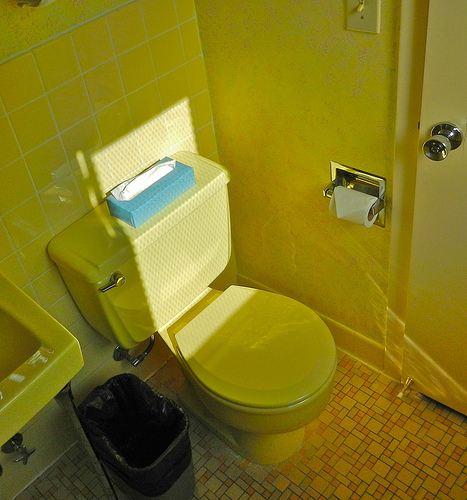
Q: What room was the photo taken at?
A: It was taken at the bathroom.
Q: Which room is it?
A: It is a bathroom.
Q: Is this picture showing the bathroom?
A: Yes, it is showing the bathroom.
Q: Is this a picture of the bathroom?
A: Yes, it is showing the bathroom.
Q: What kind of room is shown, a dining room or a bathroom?
A: It is a bathroom.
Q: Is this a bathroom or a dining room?
A: It is a bathroom.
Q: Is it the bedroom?
A: No, it is the bathroom.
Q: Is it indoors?
A: Yes, it is indoors.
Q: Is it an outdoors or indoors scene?
A: It is indoors.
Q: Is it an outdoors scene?
A: No, it is indoors.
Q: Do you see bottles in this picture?
A: No, there are no bottles.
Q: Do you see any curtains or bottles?
A: No, there are no bottles or curtains.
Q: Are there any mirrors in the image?
A: No, there are no mirrors.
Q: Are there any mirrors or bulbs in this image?
A: No, there are no mirrors or bulbs.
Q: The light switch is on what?
A: The light switch is on the wall.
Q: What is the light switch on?
A: The light switch is on the wall.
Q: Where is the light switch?
A: The light switch is in the bathroom.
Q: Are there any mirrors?
A: No, there are no mirrors.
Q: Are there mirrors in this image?
A: No, there are no mirrors.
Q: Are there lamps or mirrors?
A: No, there are no mirrors or lamps.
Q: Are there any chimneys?
A: No, there are no chimneys.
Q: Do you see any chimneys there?
A: No, there are no chimneys.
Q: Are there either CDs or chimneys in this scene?
A: No, there are no chimneys or cds.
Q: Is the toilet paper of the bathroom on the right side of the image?
A: Yes, the toilet paper is on the right of the image.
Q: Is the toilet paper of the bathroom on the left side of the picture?
A: No, the toilet paper is on the right of the image.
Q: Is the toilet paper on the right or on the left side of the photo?
A: The toilet paper is on the right of the image.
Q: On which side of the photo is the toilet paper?
A: The toilet paper is on the right of the image.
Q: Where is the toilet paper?
A: The toilet paper is in the bathroom.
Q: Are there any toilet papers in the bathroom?
A: Yes, there is a toilet paper in the bathroom.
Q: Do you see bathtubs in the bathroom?
A: No, there is a toilet paper in the bathroom.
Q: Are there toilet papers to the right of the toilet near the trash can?
A: Yes, there is a toilet paper to the right of the toilet.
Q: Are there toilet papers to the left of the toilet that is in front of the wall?
A: No, the toilet paper is to the right of the toilet.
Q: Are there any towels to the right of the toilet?
A: No, there is a toilet paper to the right of the toilet.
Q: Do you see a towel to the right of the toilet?
A: No, there is a toilet paper to the right of the toilet.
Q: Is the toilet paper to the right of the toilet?
A: Yes, the toilet paper is to the right of the toilet.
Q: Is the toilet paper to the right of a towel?
A: No, the toilet paper is to the right of the toilet.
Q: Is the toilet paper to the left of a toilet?
A: No, the toilet paper is to the right of a toilet.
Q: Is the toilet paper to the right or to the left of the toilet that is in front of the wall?
A: The toilet paper is to the right of the toilet.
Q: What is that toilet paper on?
A: The toilet paper is on the wall.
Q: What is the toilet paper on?
A: The toilet paper is on the wall.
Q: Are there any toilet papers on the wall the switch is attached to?
A: Yes, there is a toilet paper on the wall.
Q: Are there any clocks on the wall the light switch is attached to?
A: No, there is a toilet paper on the wall.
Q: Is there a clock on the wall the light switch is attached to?
A: No, there is a toilet paper on the wall.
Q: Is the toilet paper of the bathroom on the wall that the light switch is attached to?
A: Yes, the toilet paper is on the wall.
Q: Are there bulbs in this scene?
A: No, there are no bulbs.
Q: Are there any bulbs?
A: No, there are no bulbs.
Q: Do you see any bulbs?
A: No, there are no bulbs.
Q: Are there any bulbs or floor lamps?
A: No, there are no bulbs or floor lamps.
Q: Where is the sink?
A: The sink is in the bathroom.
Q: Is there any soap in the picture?
A: No, there are no soaps.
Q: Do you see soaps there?
A: No, there are no soaps.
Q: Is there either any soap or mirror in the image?
A: No, there are no soaps or mirrors.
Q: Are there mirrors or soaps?
A: No, there are no soaps or mirrors.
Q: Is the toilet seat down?
A: Yes, the toilet seat is down.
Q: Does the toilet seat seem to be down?
A: Yes, the toilet seat is down.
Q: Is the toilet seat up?
A: No, the toilet seat is down.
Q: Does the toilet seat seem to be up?
A: No, the toilet seat is down.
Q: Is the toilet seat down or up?
A: The toilet seat is down.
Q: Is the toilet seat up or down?
A: The toilet seat is down.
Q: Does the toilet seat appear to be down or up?
A: The toilet seat is down.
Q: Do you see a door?
A: Yes, there is a door.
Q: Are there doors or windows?
A: Yes, there is a door.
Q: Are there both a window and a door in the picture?
A: No, there is a door but no windows.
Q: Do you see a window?
A: No, there are no windows.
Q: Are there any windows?
A: No, there are no windows.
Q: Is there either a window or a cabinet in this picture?
A: No, there are no windows or cabinets.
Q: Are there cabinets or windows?
A: No, there are no windows or cabinets.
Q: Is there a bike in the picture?
A: No, there are no bikes.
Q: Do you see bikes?
A: No, there are no bikes.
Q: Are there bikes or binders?
A: No, there are no bikes or binders.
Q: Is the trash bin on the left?
A: Yes, the trash bin is on the left of the image.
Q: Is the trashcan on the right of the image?
A: No, the trashcan is on the left of the image.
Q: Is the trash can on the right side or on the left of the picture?
A: The trash can is on the left of the image.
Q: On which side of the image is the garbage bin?
A: The garbage bin is on the left of the image.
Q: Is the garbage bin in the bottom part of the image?
A: Yes, the garbage bin is in the bottom of the image.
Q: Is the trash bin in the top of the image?
A: No, the trash bin is in the bottom of the image.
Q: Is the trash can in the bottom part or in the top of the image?
A: The trash can is in the bottom of the image.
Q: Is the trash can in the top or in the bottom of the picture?
A: The trash can is in the bottom of the image.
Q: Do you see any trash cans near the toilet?
A: Yes, there is a trash can near the toilet.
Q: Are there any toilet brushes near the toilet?
A: No, there is a trash can near the toilet.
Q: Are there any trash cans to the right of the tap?
A: Yes, there is a trash can to the right of the tap.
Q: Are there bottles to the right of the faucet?
A: No, there is a trash can to the right of the faucet.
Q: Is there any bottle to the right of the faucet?
A: No, there is a trash can to the right of the faucet.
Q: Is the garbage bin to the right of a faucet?
A: Yes, the garbage bin is to the right of a faucet.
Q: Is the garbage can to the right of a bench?
A: No, the garbage can is to the right of a faucet.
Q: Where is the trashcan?
A: The trashcan is in the bathroom.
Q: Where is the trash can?
A: The trashcan is in the bathroom.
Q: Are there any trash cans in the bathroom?
A: Yes, there is a trash can in the bathroom.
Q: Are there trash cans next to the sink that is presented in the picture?
A: Yes, there is a trash can next to the sink.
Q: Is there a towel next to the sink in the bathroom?
A: No, there is a trash can next to the sink.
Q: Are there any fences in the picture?
A: No, there are no fences.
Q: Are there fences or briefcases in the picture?
A: No, there are no fences or briefcases.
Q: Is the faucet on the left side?
A: Yes, the faucet is on the left of the image.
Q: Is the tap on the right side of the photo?
A: No, the tap is on the left of the image.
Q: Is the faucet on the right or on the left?
A: The faucet is on the left of the image.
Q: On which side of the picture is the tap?
A: The tap is on the left of the image.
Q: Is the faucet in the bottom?
A: Yes, the faucet is in the bottom of the image.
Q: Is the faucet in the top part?
A: No, the faucet is in the bottom of the image.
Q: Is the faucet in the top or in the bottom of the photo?
A: The faucet is in the bottom of the image.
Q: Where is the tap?
A: The tap is in the bathroom.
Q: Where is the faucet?
A: The tap is in the bathroom.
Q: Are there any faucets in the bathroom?
A: Yes, there is a faucet in the bathroom.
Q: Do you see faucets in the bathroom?
A: Yes, there is a faucet in the bathroom.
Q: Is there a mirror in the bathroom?
A: No, there is a faucet in the bathroom.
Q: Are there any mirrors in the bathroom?
A: No, there is a faucet in the bathroom.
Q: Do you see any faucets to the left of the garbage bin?
A: Yes, there is a faucet to the left of the garbage bin.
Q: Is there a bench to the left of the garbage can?
A: No, there is a faucet to the left of the garbage can.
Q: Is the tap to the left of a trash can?
A: Yes, the tap is to the left of a trash can.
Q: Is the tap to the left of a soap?
A: No, the tap is to the left of a trash can.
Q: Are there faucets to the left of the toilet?
A: Yes, there is a faucet to the left of the toilet.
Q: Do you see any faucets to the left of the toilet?
A: Yes, there is a faucet to the left of the toilet.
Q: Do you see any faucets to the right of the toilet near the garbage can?
A: No, the faucet is to the left of the toilet.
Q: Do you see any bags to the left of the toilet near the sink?
A: No, there is a faucet to the left of the toilet.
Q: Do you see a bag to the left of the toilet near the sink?
A: No, there is a faucet to the left of the toilet.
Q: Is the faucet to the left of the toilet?
A: Yes, the faucet is to the left of the toilet.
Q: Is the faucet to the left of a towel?
A: No, the faucet is to the left of the toilet.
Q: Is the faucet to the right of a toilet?
A: No, the faucet is to the left of a toilet.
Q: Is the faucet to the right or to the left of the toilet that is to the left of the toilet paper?
A: The faucet is to the left of the toilet.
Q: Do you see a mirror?
A: No, there are no mirrors.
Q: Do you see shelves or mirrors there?
A: No, there are no mirrors or shelves.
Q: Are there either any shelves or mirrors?
A: No, there are no mirrors or shelves.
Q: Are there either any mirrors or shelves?
A: No, there are no mirrors or shelves.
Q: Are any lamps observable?
A: No, there are no lamps.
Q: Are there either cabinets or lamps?
A: No, there are no lamps or cabinets.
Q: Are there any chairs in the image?
A: No, there are no chairs.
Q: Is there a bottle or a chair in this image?
A: No, there are no chairs or bottles.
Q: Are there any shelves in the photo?
A: No, there are no shelves.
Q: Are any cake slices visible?
A: No, there are no cake slices.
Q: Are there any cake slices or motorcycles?
A: No, there are no cake slices or motorcycles.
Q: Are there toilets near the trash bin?
A: Yes, there is a toilet near the trash bin.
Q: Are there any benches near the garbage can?
A: No, there is a toilet near the garbage can.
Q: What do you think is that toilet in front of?
A: The toilet is in front of the wall.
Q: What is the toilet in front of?
A: The toilet is in front of the wall.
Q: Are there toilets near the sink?
A: Yes, there is a toilet near the sink.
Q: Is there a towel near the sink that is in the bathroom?
A: No, there is a toilet near the sink.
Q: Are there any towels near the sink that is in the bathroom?
A: No, there is a toilet near the sink.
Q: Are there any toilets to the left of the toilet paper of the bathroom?
A: Yes, there is a toilet to the left of the toilet paper.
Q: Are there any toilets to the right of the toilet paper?
A: No, the toilet is to the left of the toilet paper.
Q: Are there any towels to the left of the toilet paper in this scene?
A: No, there is a toilet to the left of the toilet paper.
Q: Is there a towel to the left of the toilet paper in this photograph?
A: No, there is a toilet to the left of the toilet paper.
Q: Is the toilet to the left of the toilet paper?
A: Yes, the toilet is to the left of the toilet paper.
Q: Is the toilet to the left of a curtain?
A: No, the toilet is to the left of the toilet paper.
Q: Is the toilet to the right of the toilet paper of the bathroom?
A: No, the toilet is to the left of the toilet paper.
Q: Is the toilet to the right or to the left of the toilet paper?
A: The toilet is to the left of the toilet paper.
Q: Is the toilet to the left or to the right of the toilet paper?
A: The toilet is to the left of the toilet paper.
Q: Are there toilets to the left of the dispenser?
A: Yes, there is a toilet to the left of the dispenser.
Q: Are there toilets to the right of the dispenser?
A: No, the toilet is to the left of the dispenser.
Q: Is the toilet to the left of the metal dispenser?
A: Yes, the toilet is to the left of the dispenser.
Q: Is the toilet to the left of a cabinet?
A: No, the toilet is to the left of the dispenser.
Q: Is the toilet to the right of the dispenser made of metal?
A: No, the toilet is to the left of the dispenser.